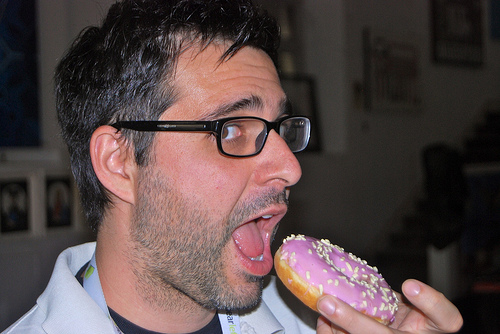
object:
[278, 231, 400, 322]
frosting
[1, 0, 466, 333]
man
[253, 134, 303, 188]
nose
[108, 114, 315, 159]
glasses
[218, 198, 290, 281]
mouth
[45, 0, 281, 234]
hair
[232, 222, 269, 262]
tongue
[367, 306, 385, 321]
sprinkles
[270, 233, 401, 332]
donut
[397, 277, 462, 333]
finger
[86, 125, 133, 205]
ear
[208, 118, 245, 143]
eye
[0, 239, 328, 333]
shirt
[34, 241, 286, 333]
collar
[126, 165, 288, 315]
beard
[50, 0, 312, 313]
head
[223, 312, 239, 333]
name